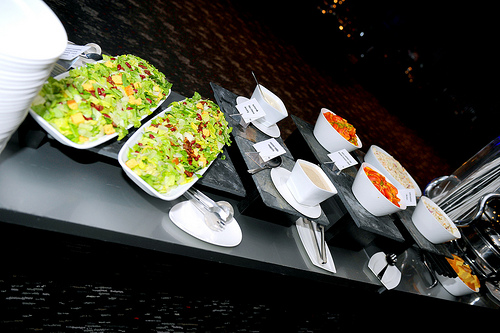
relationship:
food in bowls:
[361, 165, 403, 208] [313, 107, 362, 153]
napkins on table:
[305, 216, 335, 273] [5, 106, 471, 301]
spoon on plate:
[375, 250, 397, 282] [367, 250, 404, 290]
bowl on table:
[250, 85, 289, 127] [9, 35, 499, 315]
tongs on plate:
[296, 214, 339, 273] [294, 218, 341, 275]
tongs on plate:
[186, 187, 235, 242] [170, 199, 242, 246]